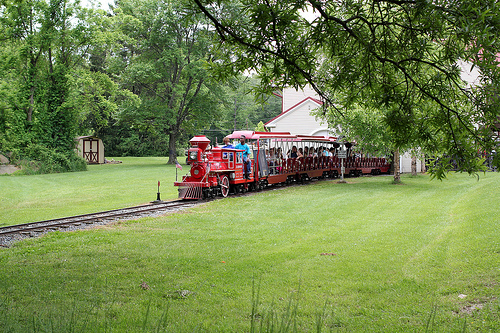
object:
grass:
[287, 203, 315, 220]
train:
[165, 122, 389, 199]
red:
[212, 165, 225, 170]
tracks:
[148, 197, 174, 212]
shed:
[71, 129, 105, 165]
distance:
[105, 71, 151, 102]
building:
[264, 71, 365, 136]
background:
[242, 76, 284, 122]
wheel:
[220, 176, 230, 197]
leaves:
[464, 12, 488, 35]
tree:
[384, 4, 483, 75]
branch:
[203, 9, 344, 40]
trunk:
[167, 138, 179, 163]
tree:
[86, 4, 240, 166]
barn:
[68, 134, 105, 163]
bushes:
[47, 118, 80, 165]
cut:
[459, 293, 480, 318]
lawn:
[303, 191, 430, 313]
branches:
[343, 13, 408, 46]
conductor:
[235, 133, 254, 175]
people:
[255, 139, 327, 169]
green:
[387, 198, 416, 214]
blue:
[241, 147, 248, 150]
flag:
[175, 162, 184, 168]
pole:
[173, 163, 179, 182]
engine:
[173, 133, 246, 201]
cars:
[248, 132, 395, 186]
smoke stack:
[190, 135, 208, 144]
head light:
[187, 150, 199, 161]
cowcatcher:
[178, 184, 206, 199]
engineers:
[221, 138, 239, 176]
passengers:
[266, 145, 378, 165]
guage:
[141, 202, 179, 210]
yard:
[42, 154, 154, 200]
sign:
[334, 142, 346, 158]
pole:
[338, 159, 347, 181]